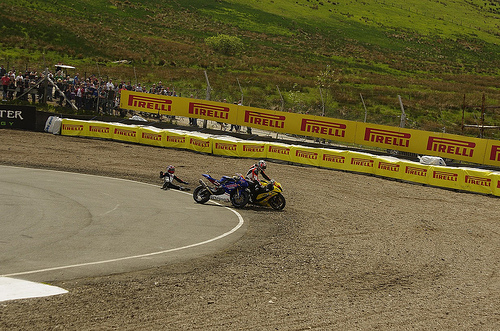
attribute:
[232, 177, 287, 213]
motorcycle — yellow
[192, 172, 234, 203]
motorcycle — blue, red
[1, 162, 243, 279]
line — stripe, paint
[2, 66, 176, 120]
people — fans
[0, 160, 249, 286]
racetrack — paved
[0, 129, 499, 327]
dirt — gravel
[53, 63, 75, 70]
umbrella — white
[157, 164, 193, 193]
man — fallen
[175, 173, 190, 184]
arm — outstretched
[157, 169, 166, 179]
arm — outstretched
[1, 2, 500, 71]
hillside — grassy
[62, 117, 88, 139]
sign — red, yellow, advertisement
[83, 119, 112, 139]
sign — red, yellow, advertisement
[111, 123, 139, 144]
sign — red, yellow, advertisement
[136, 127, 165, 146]
sign — red, yellow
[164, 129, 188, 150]
sign — red, advertisement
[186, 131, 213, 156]
sign — red, yellow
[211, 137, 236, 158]
sign — red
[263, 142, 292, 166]
sign — red, advertisement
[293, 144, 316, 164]
sign — red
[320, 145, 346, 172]
sign — red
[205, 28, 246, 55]
bush — large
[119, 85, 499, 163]
banner — yellow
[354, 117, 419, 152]
sign — red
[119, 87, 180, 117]
sign — red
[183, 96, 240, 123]
sign — red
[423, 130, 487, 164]
sign — red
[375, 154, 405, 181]
sign — red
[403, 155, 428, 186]
sign — red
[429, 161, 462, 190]
sign — red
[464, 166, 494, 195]
sign — red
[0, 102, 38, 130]
banner — black